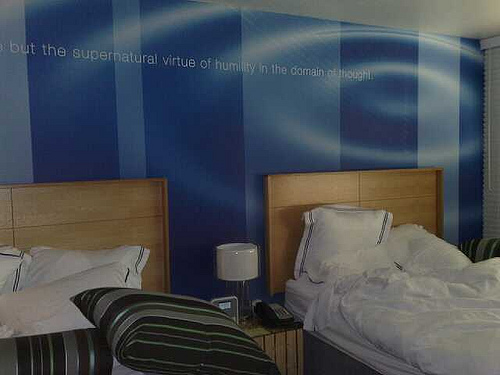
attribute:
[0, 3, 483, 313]
wall — blue, striped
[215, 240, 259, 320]
lamp — between cot, white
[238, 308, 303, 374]
nightstand — wooden, white, brown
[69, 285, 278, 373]
pillow — black, silver, gray, striped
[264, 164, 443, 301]
board — wooden, bed's, brown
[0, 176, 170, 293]
board — wooden, bed's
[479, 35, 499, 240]
blinds — horizontal, white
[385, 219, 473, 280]
pillow — in cot, white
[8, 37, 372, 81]
words — white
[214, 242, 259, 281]
shade — white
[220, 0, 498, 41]
ceiling — white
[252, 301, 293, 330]
phones — black, silver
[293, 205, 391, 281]
pillow — small, white, black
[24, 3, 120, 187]
stripe — blue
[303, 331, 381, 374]
cot — brown, unmade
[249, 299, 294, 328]
phone — black, landline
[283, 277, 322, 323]
mattress — white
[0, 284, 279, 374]
stripes — black, blue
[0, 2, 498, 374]
scene — hotel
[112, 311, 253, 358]
stripe — black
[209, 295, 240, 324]
radio — white, gray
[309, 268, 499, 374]
comforter — messy